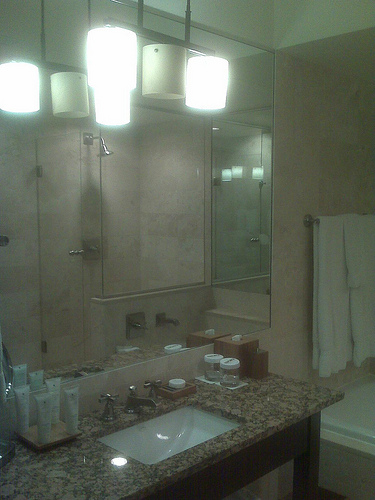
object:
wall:
[269, 54, 373, 401]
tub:
[319, 376, 373, 496]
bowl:
[93, 402, 241, 464]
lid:
[201, 352, 224, 364]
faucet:
[100, 377, 164, 422]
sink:
[94, 401, 242, 464]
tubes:
[14, 377, 80, 441]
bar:
[302, 210, 318, 227]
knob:
[98, 390, 117, 423]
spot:
[110, 455, 127, 466]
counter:
[2, 373, 343, 497]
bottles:
[10, 370, 31, 443]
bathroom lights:
[81, 27, 152, 126]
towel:
[337, 213, 373, 360]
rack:
[303, 210, 337, 230]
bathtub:
[313, 388, 374, 451]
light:
[107, 452, 129, 471]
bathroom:
[9, 10, 356, 478]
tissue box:
[213, 332, 269, 378]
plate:
[17, 419, 80, 447]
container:
[34, 394, 52, 443]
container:
[59, 384, 83, 430]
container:
[47, 373, 64, 424]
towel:
[311, 210, 351, 370]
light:
[178, 40, 231, 115]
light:
[139, 39, 194, 106]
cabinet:
[221, 452, 319, 499]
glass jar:
[202, 351, 219, 381]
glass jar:
[219, 353, 241, 387]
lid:
[219, 355, 240, 365]